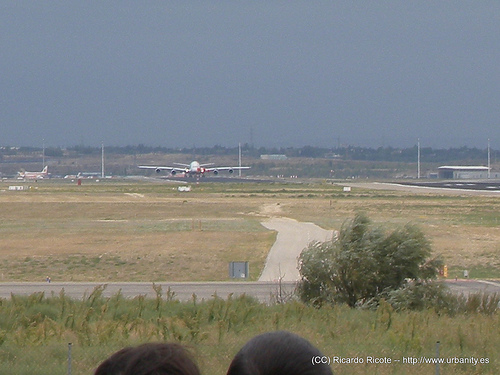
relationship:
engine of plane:
[213, 170, 219, 175] [134, 151, 253, 186]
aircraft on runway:
[137, 161, 252, 181] [402, 175, 498, 191]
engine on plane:
[225, 168, 236, 175] [136, 153, 256, 190]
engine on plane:
[227, 168, 234, 174] [136, 157, 253, 177]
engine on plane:
[211, 167, 219, 177] [136, 157, 253, 177]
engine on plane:
[167, 165, 179, 177] [136, 157, 253, 177]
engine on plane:
[155, 168, 161, 173] [136, 157, 253, 177]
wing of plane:
[134, 161, 182, 175] [134, 157, 249, 180]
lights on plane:
[188, 165, 209, 176] [139, 159, 248, 186]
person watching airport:
[218, 330, 330, 373] [7, 99, 499, 311]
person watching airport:
[92, 342, 204, 374] [7, 99, 499, 311]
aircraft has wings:
[136, 158, 254, 180] [138, 165, 251, 173]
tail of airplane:
[194, 166, 204, 175] [134, 157, 257, 186]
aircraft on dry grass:
[12, 164, 57, 184] [0, 180, 499, 284]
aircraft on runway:
[137, 161, 252, 181] [181, 179, 335, 280]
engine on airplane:
[227, 168, 234, 174] [137, 158, 255, 179]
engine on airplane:
[213, 170, 219, 175] [137, 158, 255, 179]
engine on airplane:
[168, 170, 176, 177] [137, 158, 255, 179]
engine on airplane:
[155, 165, 160, 175] [137, 158, 255, 179]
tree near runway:
[295, 212, 450, 316] [13, 278, 497, 313]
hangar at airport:
[421, 147, 482, 189] [0, 150, 498, 190]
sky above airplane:
[3, 0, 499, 152] [134, 144, 257, 203]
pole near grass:
[441, 262, 450, 276] [0, 181, 498, 373]